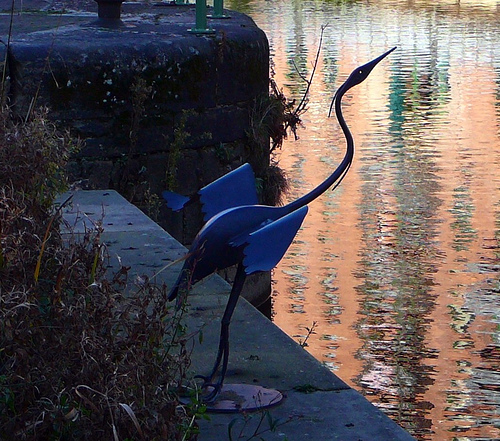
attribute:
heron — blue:
[186, 92, 333, 387]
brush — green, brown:
[0, 90, 205, 437]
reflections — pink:
[352, 75, 467, 297]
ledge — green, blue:
[70, 184, 335, 404]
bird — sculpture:
[161, 45, 398, 412]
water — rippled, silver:
[262, 3, 497, 439]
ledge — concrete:
[128, 184, 256, 346]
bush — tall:
[0, 191, 194, 436]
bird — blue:
[123, 33, 468, 391]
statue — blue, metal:
[158, 42, 401, 413]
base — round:
[173, 378, 285, 414]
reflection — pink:
[241, 15, 494, 439]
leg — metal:
[217, 271, 251, 393]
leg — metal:
[199, 267, 241, 393]